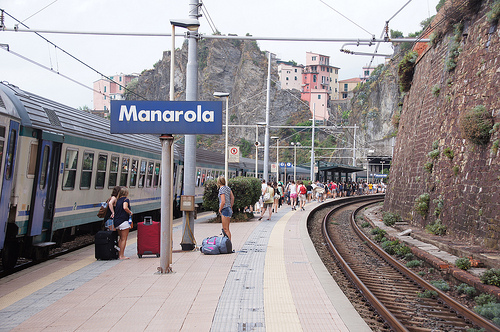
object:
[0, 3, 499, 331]
scene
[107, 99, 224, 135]
sign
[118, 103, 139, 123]
letters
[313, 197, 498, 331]
train tracks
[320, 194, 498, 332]
curve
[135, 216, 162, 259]
suitcase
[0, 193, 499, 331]
ground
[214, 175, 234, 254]
woman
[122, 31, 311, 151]
rock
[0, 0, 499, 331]
city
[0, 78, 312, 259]
train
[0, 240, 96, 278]
tracks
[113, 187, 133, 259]
woman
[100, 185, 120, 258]
woman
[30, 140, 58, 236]
door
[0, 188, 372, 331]
platform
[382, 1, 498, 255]
wall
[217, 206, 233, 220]
shorts